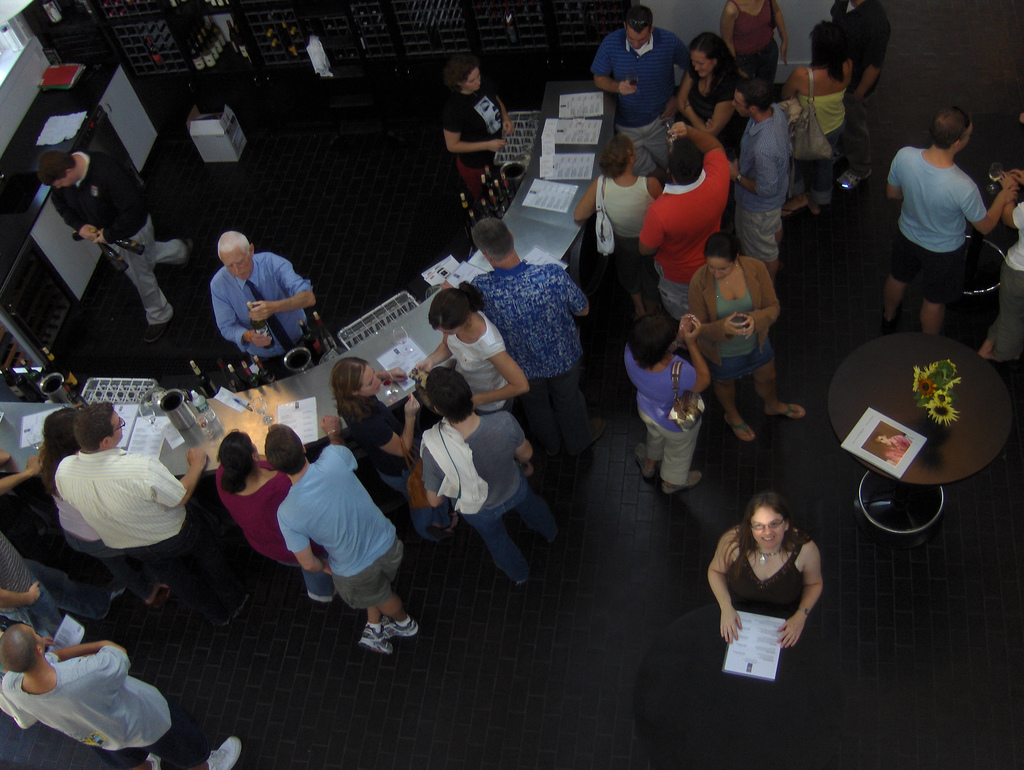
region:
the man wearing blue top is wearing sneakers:
[363, 625, 414, 654]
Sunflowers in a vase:
[890, 340, 989, 465]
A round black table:
[821, 306, 1019, 526]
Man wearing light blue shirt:
[238, 417, 413, 598]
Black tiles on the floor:
[423, 622, 629, 729]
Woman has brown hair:
[700, 482, 830, 614]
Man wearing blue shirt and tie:
[195, 230, 343, 378]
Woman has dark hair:
[423, 277, 522, 405]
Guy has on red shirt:
[618, 129, 752, 279]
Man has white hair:
[195, 203, 294, 349]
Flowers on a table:
[864, 314, 996, 458]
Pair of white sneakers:
[324, 608, 442, 664]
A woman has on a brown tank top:
[694, 483, 834, 642]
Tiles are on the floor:
[429, 613, 600, 730]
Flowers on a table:
[879, 342, 972, 435]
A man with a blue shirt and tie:
[181, 231, 329, 369]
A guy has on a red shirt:
[628, 112, 745, 295]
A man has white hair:
[193, 225, 269, 299]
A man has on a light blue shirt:
[243, 442, 447, 623]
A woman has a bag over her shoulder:
[634, 284, 729, 510]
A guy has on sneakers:
[310, 592, 462, 687]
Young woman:
[692, 495, 830, 737]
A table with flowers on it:
[809, 317, 1019, 543]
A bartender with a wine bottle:
[209, 220, 336, 382]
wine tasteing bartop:
[5, 354, 335, 485]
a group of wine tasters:
[562, 8, 804, 309]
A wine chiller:
[148, 386, 216, 456]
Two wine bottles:
[76, 219, 165, 278]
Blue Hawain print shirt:
[473, 257, 594, 388]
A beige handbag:
[783, 59, 840, 178]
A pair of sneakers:
[345, 605, 429, 664]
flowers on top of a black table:
[893, 345, 1005, 444]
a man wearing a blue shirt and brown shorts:
[252, 418, 445, 663]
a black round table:
[815, 308, 1018, 587]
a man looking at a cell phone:
[593, 11, 698, 167]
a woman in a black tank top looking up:
[695, 481, 841, 694]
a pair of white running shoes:
[347, 602, 431, 670]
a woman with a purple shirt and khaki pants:
[626, 301, 725, 504]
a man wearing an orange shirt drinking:
[632, 112, 735, 231]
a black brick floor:
[255, 645, 509, 750]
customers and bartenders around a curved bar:
[24, 84, 710, 612]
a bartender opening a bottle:
[202, 226, 320, 357]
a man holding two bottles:
[29, 143, 197, 347]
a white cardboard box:
[179, 105, 250, 162]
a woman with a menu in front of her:
[699, 487, 826, 684]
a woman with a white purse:
[568, 130, 660, 260]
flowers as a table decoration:
[907, 351, 969, 429]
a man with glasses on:
[69, 397, 136, 452]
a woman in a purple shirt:
[206, 427, 301, 565]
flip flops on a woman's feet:
[718, 400, 816, 440]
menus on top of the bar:
[515, 87, 598, 217]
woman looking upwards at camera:
[708, 491, 825, 676]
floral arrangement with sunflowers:
[909, 354, 967, 427]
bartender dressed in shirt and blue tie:
[206, 227, 317, 351]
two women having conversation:
[620, 231, 811, 494]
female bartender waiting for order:
[433, 55, 514, 191]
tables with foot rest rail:
[822, 328, 1007, 554]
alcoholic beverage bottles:
[183, 354, 276, 393]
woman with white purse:
[619, 307, 711, 494]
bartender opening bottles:
[32, 139, 200, 343]